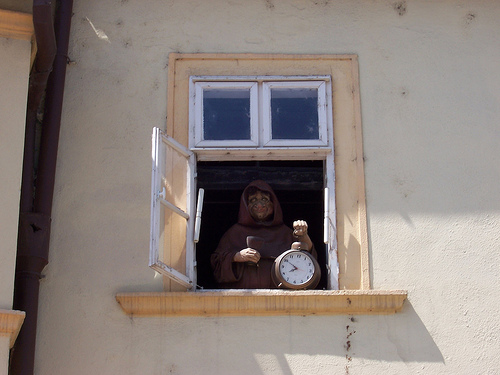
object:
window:
[260, 77, 330, 149]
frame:
[186, 77, 330, 149]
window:
[193, 81, 262, 149]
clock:
[271, 251, 322, 290]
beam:
[5, 1, 70, 374]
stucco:
[0, 0, 494, 375]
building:
[0, 0, 500, 373]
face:
[246, 185, 273, 220]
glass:
[272, 91, 316, 141]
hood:
[236, 182, 282, 228]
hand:
[234, 248, 260, 265]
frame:
[163, 147, 363, 291]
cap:
[240, 236, 274, 248]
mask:
[243, 190, 274, 220]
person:
[215, 181, 314, 287]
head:
[240, 180, 277, 221]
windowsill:
[114, 286, 409, 315]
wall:
[1, 0, 499, 374]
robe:
[221, 221, 299, 289]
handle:
[290, 224, 302, 240]